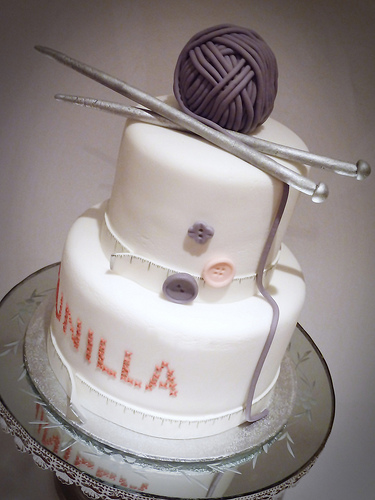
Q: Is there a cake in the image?
A: Yes, there is a cake.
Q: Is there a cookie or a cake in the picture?
A: Yes, there is a cake.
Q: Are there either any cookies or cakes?
A: Yes, there is a cake.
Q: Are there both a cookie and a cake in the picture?
A: No, there is a cake but no cookies.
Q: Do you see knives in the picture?
A: No, there are no knives.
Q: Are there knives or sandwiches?
A: No, there are no knives or sandwiches.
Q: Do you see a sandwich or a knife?
A: No, there are no knives or sandwiches.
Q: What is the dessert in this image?
A: The dessert is a cake.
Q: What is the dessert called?
A: The dessert is a cake.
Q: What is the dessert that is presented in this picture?
A: The dessert is a cake.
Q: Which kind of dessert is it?
A: The dessert is a cake.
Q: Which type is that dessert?
A: This is a cake.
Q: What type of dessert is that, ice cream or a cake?
A: This is a cake.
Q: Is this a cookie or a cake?
A: This is a cake.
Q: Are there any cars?
A: No, there are no cars.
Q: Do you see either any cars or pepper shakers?
A: No, there are no cars or pepper shakers.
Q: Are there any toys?
A: No, there are no toys.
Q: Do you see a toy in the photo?
A: No, there are no toys.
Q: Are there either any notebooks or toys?
A: No, there are no toys or notebooks.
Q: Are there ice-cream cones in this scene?
A: No, there are no ice-cream cones.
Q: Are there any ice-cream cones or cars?
A: No, there are no ice-cream cones or cars.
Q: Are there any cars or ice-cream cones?
A: No, there are no ice-cream cones or cars.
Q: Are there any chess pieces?
A: No, there are no chess pieces.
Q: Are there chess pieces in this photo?
A: No, there are no chess pieces.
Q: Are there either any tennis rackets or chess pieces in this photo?
A: No, there are no chess pieces or tennis rackets.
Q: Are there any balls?
A: Yes, there is a ball.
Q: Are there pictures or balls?
A: Yes, there is a ball.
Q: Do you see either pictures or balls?
A: Yes, there is a ball.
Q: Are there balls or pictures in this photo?
A: Yes, there is a ball.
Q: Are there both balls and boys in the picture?
A: No, there is a ball but no boys.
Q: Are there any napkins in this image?
A: No, there are no napkins.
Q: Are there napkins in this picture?
A: No, there are no napkins.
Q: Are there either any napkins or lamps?
A: No, there are no napkins or lamps.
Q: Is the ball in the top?
A: Yes, the ball is in the top of the image.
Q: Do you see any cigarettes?
A: No, there are no cigarettes.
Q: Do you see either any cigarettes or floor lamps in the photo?
A: No, there are no cigarettes or floor lamps.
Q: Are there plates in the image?
A: Yes, there is a plate.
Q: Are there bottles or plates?
A: Yes, there is a plate.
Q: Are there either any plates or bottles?
A: Yes, there is a plate.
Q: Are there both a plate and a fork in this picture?
A: No, there is a plate but no forks.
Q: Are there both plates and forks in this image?
A: No, there is a plate but no forks.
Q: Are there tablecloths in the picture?
A: No, there are no tablecloths.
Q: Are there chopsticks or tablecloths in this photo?
A: No, there are no tablecloths or chopsticks.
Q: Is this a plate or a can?
A: This is a plate.